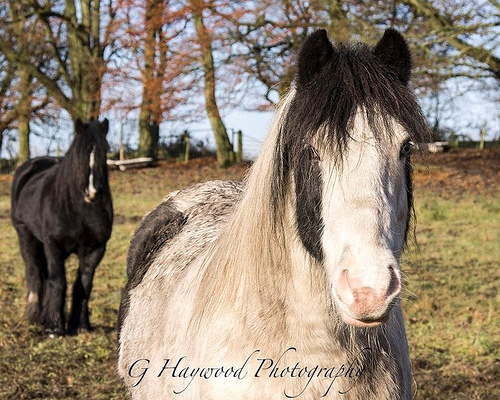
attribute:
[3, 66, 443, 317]
horses — 2, black, white, paired, photographed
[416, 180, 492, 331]
field — grassy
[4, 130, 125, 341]
horse — large, black, white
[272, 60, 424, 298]
horse — large, white, black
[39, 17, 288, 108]
trees — brown, distant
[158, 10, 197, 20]
leaves — brown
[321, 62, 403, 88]
mane — gray, black, white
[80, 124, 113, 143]
mane — black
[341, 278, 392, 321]
nose — white, pink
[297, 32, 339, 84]
ear — black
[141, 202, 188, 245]
markings — black, white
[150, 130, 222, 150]
fence — distant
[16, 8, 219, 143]
group — small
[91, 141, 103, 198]
markings — white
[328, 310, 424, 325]
mouth — pink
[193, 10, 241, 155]
tree — brown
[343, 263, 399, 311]
nose — pink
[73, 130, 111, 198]
face — black, white